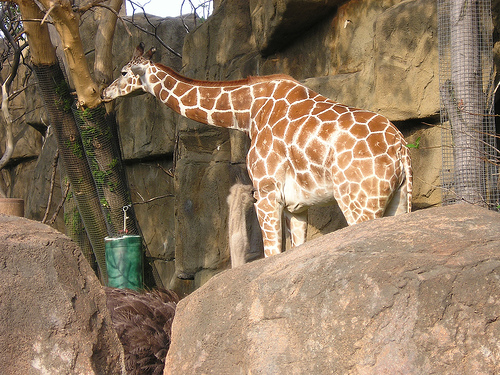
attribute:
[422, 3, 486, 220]
fencing — gray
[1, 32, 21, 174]
branch — curved, bare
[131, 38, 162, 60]
horns — small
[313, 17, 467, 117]
rock — tan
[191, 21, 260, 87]
rock — tan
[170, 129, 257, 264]
rock — tan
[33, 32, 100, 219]
rock — tan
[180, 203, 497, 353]
boulder — LARGE, RED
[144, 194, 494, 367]
boulder — gray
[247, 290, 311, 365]
highlights — pink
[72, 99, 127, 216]
leaves — green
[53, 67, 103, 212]
leaves — green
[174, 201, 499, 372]
rocks — BIG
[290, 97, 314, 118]
spots — BROWN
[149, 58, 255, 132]
neck — LONG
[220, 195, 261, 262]
ostrich neck — LONG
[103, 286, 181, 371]
feathers — BROWN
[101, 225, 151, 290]
bucket — GREEN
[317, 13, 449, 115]
wall — BROWN, ROCK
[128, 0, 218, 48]
branches — tree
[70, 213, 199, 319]
container — green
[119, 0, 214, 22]
sky — CLOUDY, GREY